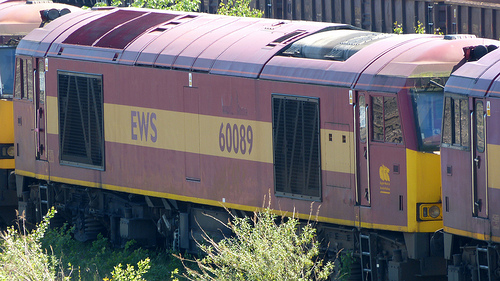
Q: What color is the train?
A: Red and yellow.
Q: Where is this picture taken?
A: A railway.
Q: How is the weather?
A: Sunny.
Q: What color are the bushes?
A: Green.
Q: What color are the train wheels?
A: Black.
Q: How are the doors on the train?
A: Open.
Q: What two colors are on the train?
A: Yellow and maroon.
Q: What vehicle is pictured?
A: A train.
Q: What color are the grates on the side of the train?
A: Black.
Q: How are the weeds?
A: Overgrown.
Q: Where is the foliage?
A: Beside the train tracks.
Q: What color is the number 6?
A: Black.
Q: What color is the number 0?
A: Black.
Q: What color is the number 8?
A: Black.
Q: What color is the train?
A: Purple and yellow.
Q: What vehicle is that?
A: A train.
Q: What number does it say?
A: 60089.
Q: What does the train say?
A: EWS.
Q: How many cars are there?
A: Three.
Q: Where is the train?
A: The woods.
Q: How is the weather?
A: Sunny.